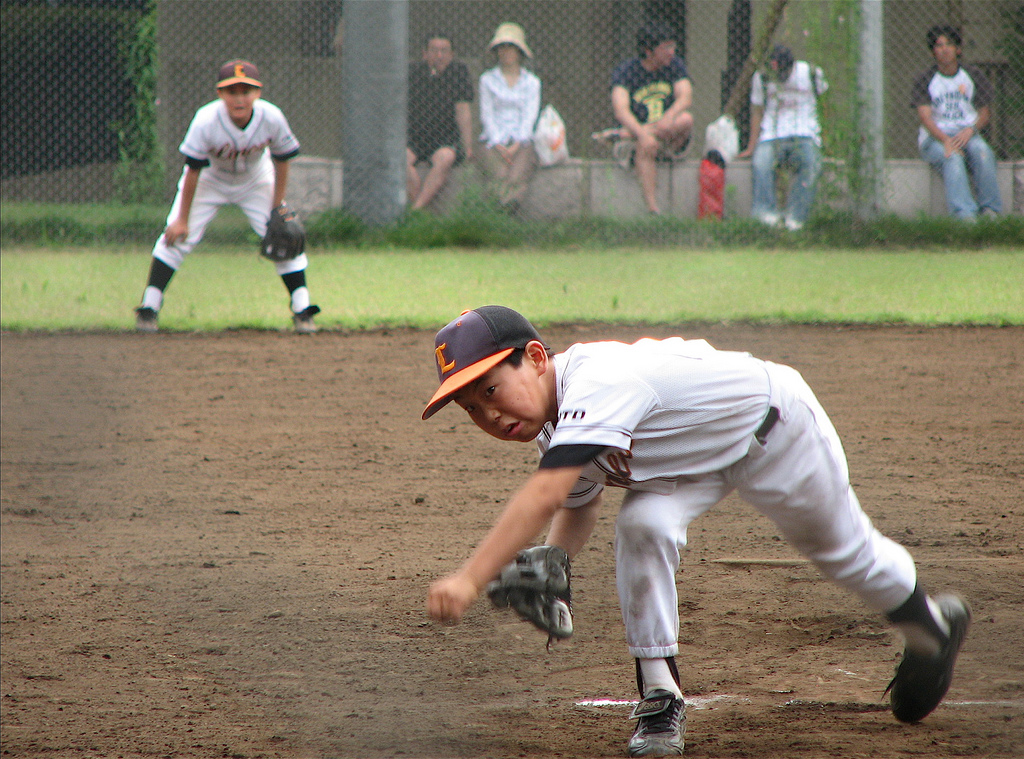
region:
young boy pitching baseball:
[407, 294, 977, 754]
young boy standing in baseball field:
[122, 55, 334, 334]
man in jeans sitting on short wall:
[904, 17, 1012, 233]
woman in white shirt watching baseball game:
[471, 10, 549, 235]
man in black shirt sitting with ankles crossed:
[398, 25, 482, 235]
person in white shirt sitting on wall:
[727, 36, 842, 243]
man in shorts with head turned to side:
[586, 17, 701, 226]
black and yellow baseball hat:
[414, 298, 547, 426]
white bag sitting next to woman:
[523, 98, 578, 169]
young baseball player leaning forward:
[126, 50, 335, 341]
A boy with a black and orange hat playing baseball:
[133, 56, 323, 338]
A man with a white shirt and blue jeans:
[908, 25, 1011, 232]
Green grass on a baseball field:
[0, 243, 1022, 338]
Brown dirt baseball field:
[2, 331, 1018, 756]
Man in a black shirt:
[399, 29, 477, 214]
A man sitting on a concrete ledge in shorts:
[595, 25, 697, 225]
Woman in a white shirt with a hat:
[475, 23, 545, 230]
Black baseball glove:
[487, 549, 577, 644]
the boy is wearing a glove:
[416, 304, 968, 753]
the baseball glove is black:
[485, 543, 575, 654]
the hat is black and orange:
[422, 303, 547, 418]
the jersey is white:
[531, 332, 773, 507]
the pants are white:
[615, 356, 914, 657]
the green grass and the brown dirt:
[1, 244, 1022, 754]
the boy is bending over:
[133, 62, 324, 334]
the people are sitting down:
[403, 18, 1001, 233]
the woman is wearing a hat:
[478, 21, 539, 219]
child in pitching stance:
[401, 300, 970, 756]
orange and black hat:
[423, 308, 521, 422]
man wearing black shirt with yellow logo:
[607, 16, 699, 212]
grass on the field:
[4, 228, 1016, 311]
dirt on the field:
[7, 326, 1001, 753]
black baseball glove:
[489, 557, 576, 638]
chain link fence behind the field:
[12, 10, 1012, 258]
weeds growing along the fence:
[3, 187, 1022, 242]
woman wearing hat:
[483, 10, 554, 206]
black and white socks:
[145, 247, 313, 314]